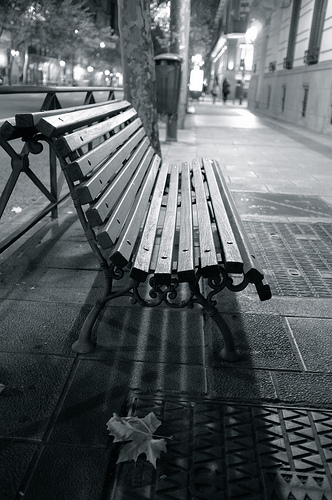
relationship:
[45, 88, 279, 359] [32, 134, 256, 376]
bench with support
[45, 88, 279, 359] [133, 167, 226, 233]
bench with support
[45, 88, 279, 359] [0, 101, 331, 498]
bench on sidewalk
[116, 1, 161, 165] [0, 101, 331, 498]
trunk growing through sidewalk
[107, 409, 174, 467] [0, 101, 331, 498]
leaf on sidewalk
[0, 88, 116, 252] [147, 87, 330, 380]
fence along sidewalk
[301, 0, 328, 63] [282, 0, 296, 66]
window covered with bars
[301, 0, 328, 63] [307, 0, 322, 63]
window covered with bars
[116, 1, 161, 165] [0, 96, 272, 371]
trunk next to bench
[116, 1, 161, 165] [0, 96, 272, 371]
trunk next bench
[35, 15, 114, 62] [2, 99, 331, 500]
trees side sidewalk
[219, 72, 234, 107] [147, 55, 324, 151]
person on sidewalk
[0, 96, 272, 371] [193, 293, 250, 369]
bench has leg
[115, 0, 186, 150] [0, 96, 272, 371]
tree across bench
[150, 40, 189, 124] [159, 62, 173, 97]
bin for items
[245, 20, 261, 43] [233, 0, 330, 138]
lights on building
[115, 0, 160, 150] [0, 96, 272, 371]
tree by bench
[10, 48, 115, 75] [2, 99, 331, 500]
lights on sidewalk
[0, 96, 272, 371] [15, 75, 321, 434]
bench on sidewalk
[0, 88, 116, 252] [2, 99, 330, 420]
fence that separates sidewalk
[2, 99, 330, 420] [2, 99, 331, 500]
sidewalk from sidewalk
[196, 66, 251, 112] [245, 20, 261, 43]
people walking under lights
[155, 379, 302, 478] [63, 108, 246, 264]
hole next to bench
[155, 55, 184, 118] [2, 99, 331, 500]
bin on sidewalk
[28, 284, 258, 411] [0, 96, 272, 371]
shadow on bench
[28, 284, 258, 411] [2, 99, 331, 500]
shadow on sidewalk